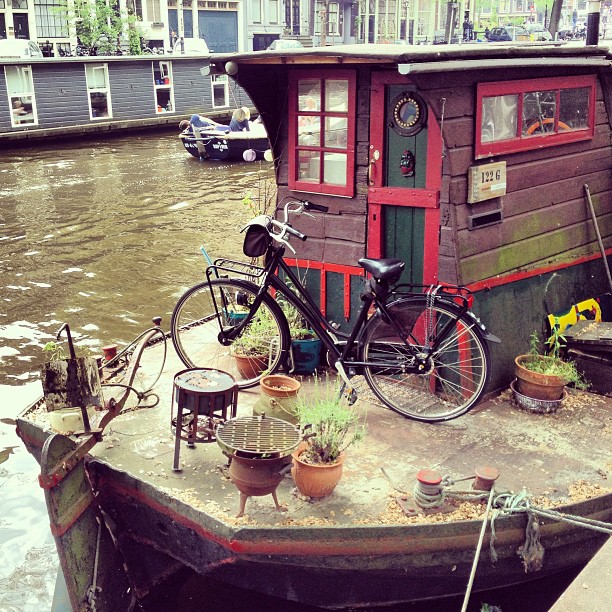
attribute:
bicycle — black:
[168, 210, 484, 412]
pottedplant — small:
[514, 329, 569, 398]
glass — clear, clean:
[322, 116, 348, 149]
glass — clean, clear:
[322, 148, 347, 188]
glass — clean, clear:
[295, 150, 322, 184]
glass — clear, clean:
[212, 67, 226, 107]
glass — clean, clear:
[155, 59, 171, 113]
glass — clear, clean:
[78, 64, 108, 116]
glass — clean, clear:
[0, 66, 34, 126]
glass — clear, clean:
[33, 5, 64, 35]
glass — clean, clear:
[293, 75, 323, 112]